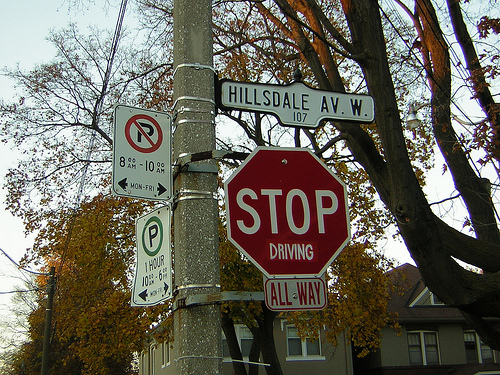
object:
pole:
[171, 5, 224, 375]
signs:
[111, 79, 375, 311]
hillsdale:
[228, 85, 363, 117]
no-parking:
[124, 113, 163, 153]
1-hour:
[141, 254, 168, 287]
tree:
[25, 195, 170, 374]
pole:
[42, 270, 58, 375]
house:
[355, 263, 497, 375]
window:
[406, 331, 441, 366]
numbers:
[120, 156, 166, 174]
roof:
[382, 262, 478, 323]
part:
[68, 285, 124, 358]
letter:
[235, 188, 338, 234]